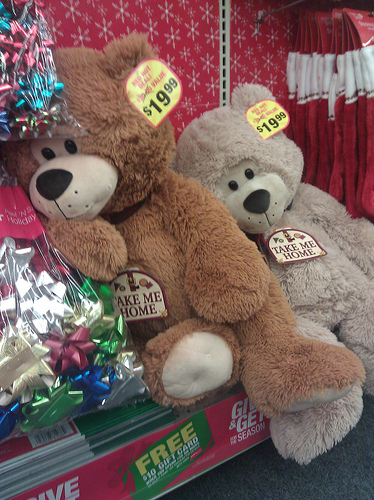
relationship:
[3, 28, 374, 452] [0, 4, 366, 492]
two bags are at store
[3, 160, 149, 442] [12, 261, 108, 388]
plastic bag filled with bows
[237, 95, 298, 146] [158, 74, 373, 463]
tag on teddy bear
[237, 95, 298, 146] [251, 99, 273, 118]
tag says take me home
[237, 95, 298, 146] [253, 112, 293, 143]
tag says 19.99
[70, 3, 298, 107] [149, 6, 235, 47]
paper for christmas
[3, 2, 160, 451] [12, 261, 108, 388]
two bags of bows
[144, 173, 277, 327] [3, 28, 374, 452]
arm of two bags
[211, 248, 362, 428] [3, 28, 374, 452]
leg of two bags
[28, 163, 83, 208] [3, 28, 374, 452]
nose of two bags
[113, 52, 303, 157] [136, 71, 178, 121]
two tags show price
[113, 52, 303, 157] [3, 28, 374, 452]
two tags are on two bags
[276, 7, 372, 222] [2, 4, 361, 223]
stockings are on wall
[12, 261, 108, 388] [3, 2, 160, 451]
bows are in two bags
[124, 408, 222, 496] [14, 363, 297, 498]
sticker on bottom of ledge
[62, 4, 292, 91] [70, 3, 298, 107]
snowflake pattern on paper